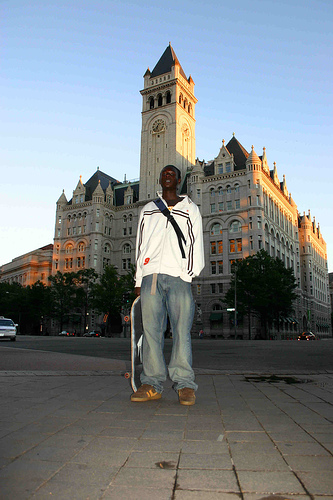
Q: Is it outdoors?
A: Yes, it is outdoors.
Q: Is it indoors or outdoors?
A: It is outdoors.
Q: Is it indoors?
A: No, it is outdoors.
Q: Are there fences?
A: No, there are no fences.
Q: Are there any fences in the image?
A: No, there are no fences.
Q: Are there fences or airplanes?
A: No, there are no fences or airplanes.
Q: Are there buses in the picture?
A: No, there are no buses.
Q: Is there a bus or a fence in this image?
A: No, there are no buses or fences.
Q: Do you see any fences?
A: No, there are no fences.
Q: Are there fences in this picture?
A: No, there are no fences.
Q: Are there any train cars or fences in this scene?
A: No, there are no fences or train cars.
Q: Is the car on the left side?
A: Yes, the car is on the left of the image.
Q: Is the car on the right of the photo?
A: No, the car is on the left of the image.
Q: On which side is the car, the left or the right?
A: The car is on the left of the image.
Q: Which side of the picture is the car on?
A: The car is on the left of the image.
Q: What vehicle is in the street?
A: The vehicle is a car.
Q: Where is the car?
A: The car is in the street.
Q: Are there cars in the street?
A: Yes, there is a car in the street.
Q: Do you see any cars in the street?
A: Yes, there is a car in the street.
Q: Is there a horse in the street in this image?
A: No, there is a car in the street.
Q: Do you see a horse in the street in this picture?
A: No, there is a car in the street.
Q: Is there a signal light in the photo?
A: No, there are no traffic lights.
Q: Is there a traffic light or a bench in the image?
A: No, there are no traffic lights or benches.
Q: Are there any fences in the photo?
A: No, there are no fences.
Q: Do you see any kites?
A: No, there are no kites.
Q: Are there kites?
A: No, there are no kites.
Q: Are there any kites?
A: No, there are no kites.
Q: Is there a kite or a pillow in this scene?
A: No, there are no kites or pillows.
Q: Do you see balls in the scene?
A: No, there are no balls.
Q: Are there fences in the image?
A: No, there are no fences.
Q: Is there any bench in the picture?
A: No, there are no benches.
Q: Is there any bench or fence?
A: No, there are no benches or fences.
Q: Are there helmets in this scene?
A: No, there are no helmets.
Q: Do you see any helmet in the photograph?
A: No, there are no helmets.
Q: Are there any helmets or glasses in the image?
A: No, there are no helmets or glasses.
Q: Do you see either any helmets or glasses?
A: No, there are no helmets or glasses.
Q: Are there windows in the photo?
A: Yes, there are windows.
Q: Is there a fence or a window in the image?
A: Yes, there are windows.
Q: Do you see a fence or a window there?
A: Yes, there are windows.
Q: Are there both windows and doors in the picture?
A: No, there are windows but no doors.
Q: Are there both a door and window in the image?
A: No, there are windows but no doors.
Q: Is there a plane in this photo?
A: No, there are no airplanes.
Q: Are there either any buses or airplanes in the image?
A: No, there are no airplanes or buses.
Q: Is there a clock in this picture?
A: Yes, there is a clock.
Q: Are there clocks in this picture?
A: Yes, there is a clock.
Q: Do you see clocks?
A: Yes, there is a clock.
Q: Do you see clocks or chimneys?
A: Yes, there is a clock.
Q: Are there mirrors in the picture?
A: No, there are no mirrors.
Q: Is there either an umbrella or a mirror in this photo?
A: No, there are no mirrors or umbrellas.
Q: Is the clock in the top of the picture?
A: Yes, the clock is in the top of the image.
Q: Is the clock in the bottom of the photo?
A: No, the clock is in the top of the image.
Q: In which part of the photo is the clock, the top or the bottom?
A: The clock is in the top of the image.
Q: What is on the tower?
A: The clock is on the tower.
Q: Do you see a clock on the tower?
A: Yes, there is a clock on the tower.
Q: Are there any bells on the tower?
A: No, there is a clock on the tower.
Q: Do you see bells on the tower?
A: No, there is a clock on the tower.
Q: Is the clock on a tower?
A: Yes, the clock is on a tower.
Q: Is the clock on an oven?
A: No, the clock is on a tower.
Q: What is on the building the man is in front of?
A: The clock is on the building.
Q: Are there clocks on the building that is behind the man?
A: Yes, there is a clock on the building.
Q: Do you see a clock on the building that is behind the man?
A: Yes, there is a clock on the building.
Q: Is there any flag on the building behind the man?
A: No, there is a clock on the building.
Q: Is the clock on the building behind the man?
A: Yes, the clock is on the building.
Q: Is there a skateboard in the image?
A: Yes, there is a skateboard.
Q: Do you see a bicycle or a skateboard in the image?
A: Yes, there is a skateboard.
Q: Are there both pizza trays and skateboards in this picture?
A: No, there is a skateboard but no pizza trays.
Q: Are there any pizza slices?
A: No, there are no pizza slices.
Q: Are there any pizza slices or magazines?
A: No, there are no pizza slices or magazines.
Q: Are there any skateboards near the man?
A: Yes, there is a skateboard near the man.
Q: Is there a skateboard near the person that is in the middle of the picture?
A: Yes, there is a skateboard near the man.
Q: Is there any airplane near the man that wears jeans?
A: No, there is a skateboard near the man.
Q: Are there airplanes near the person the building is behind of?
A: No, there is a skateboard near the man.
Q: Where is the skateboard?
A: The skateboard is on the side walk.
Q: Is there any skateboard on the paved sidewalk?
A: Yes, there is a skateboard on the sidewalk.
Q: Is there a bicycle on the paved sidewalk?
A: No, there is a skateboard on the sidewalk.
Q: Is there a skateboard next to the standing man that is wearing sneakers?
A: Yes, there is a skateboard next to the man.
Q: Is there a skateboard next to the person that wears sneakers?
A: Yes, there is a skateboard next to the man.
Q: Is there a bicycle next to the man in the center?
A: No, there is a skateboard next to the man.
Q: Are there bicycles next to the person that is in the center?
A: No, there is a skateboard next to the man.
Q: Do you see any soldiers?
A: No, there are no soldiers.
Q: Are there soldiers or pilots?
A: No, there are no soldiers or pilots.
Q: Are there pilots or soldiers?
A: No, there are no soldiers or pilots.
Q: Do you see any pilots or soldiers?
A: No, there are no soldiers or pilots.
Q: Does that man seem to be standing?
A: Yes, the man is standing.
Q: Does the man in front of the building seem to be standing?
A: Yes, the man is standing.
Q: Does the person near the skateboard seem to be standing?
A: Yes, the man is standing.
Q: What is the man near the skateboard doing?
A: The man is standing.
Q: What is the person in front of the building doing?
A: The man is standing.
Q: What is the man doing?
A: The man is standing.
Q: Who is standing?
A: The man is standing.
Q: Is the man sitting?
A: No, the man is standing.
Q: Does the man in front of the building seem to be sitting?
A: No, the man is standing.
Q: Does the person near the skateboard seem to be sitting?
A: No, the man is standing.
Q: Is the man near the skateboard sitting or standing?
A: The man is standing.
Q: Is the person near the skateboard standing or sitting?
A: The man is standing.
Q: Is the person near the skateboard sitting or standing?
A: The man is standing.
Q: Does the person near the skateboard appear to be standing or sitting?
A: The man is standing.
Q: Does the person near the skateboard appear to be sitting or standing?
A: The man is standing.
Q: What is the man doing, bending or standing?
A: The man is standing.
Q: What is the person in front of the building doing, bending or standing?
A: The man is standing.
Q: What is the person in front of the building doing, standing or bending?
A: The man is standing.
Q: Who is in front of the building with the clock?
A: The man is in front of the building.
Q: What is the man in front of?
A: The man is in front of the building.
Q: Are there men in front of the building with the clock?
A: Yes, there is a man in front of the building.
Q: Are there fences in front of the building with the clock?
A: No, there is a man in front of the building.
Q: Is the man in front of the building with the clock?
A: Yes, the man is in front of the building.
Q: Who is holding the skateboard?
A: The man is holding the skateboard.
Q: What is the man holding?
A: The man is holding the skateboard.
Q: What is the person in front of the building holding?
A: The man is holding the skateboard.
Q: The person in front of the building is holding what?
A: The man is holding the skateboard.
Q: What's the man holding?
A: The man is holding the skateboard.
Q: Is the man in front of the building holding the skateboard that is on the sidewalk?
A: Yes, the man is holding the skateboard.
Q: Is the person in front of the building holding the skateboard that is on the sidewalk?
A: Yes, the man is holding the skateboard.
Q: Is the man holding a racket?
A: No, the man is holding the skateboard.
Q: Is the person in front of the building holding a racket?
A: No, the man is holding the skateboard.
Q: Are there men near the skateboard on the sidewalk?
A: Yes, there is a man near the skateboard.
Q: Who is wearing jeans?
A: The man is wearing jeans.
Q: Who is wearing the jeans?
A: The man is wearing jeans.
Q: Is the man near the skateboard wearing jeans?
A: Yes, the man is wearing jeans.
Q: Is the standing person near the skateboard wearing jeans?
A: Yes, the man is wearing jeans.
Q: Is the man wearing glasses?
A: No, the man is wearing jeans.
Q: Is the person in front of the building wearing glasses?
A: No, the man is wearing jeans.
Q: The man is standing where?
A: The man is standing on the side walk.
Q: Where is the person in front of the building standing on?
A: The man is standing on the side walk.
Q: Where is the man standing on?
A: The man is standing on the side walk.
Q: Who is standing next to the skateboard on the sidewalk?
A: The man is standing next to the skateboard.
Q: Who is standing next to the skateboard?
A: The man is standing next to the skateboard.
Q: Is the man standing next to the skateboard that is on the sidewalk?
A: Yes, the man is standing next to the skateboard.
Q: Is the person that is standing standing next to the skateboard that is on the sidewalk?
A: Yes, the man is standing next to the skateboard.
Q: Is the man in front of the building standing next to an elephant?
A: No, the man is standing next to the skateboard.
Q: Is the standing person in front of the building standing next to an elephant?
A: No, the man is standing next to the skateboard.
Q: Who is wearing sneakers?
A: The man is wearing sneakers.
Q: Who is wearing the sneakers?
A: The man is wearing sneakers.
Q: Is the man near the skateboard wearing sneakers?
A: Yes, the man is wearing sneakers.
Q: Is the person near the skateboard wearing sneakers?
A: Yes, the man is wearing sneakers.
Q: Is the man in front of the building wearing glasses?
A: No, the man is wearing sneakers.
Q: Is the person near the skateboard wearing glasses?
A: No, the man is wearing sneakers.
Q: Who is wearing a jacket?
A: The man is wearing a jacket.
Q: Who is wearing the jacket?
A: The man is wearing a jacket.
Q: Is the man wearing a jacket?
A: Yes, the man is wearing a jacket.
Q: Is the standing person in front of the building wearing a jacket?
A: Yes, the man is wearing a jacket.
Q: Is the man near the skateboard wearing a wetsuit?
A: No, the man is wearing a jacket.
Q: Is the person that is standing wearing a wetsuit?
A: No, the man is wearing a jacket.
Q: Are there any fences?
A: No, there are no fences.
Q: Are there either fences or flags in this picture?
A: No, there are no fences or flags.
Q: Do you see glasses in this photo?
A: No, there are no glasses.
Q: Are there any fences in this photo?
A: No, there are no fences.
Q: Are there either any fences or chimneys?
A: No, there are no fences or chimneys.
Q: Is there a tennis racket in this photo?
A: No, there are no rackets.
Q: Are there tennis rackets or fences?
A: No, there are no tennis rackets or fences.